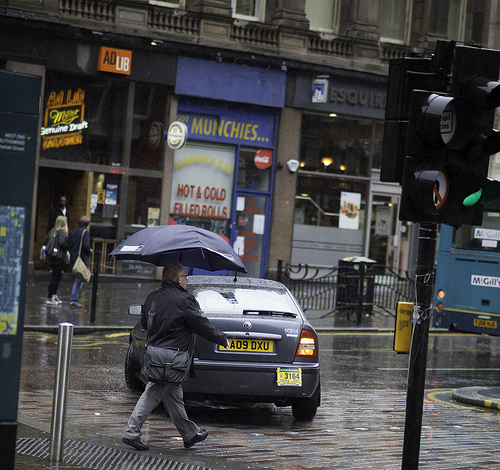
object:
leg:
[163, 378, 209, 448]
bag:
[139, 340, 192, 385]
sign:
[40, 81, 88, 154]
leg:
[122, 367, 174, 454]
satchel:
[138, 294, 195, 386]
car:
[122, 273, 322, 423]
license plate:
[212, 336, 274, 353]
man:
[119, 251, 230, 453]